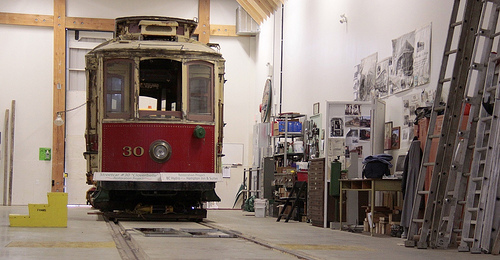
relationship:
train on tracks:
[77, 11, 232, 223] [103, 218, 307, 258]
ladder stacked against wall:
[398, 95, 438, 245] [286, 17, 359, 87]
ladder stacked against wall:
[473, 81, 497, 240] [286, 17, 359, 87]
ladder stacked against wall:
[457, 56, 500, 253] [286, 17, 359, 87]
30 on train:
[121, 139, 143, 159] [77, 11, 232, 223]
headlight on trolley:
[147, 139, 168, 160] [71, 10, 231, 225]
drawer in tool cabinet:
[308, 161, 323, 170] [306, 158, 325, 227]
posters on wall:
[328, 35, 463, 117] [339, 22, 449, 125]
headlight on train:
[152, 144, 172, 161] [83, 15, 227, 209]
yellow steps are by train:
[8, 192, 70, 228] [83, 15, 227, 209]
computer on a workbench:
[390, 151, 409, 178] [337, 177, 400, 239]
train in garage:
[83, 15, 227, 209] [5, 6, 497, 257]